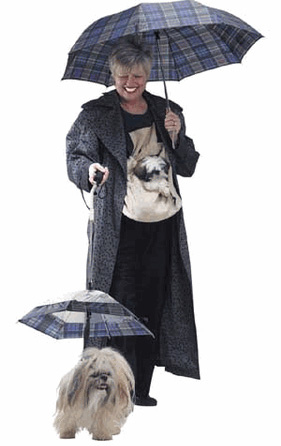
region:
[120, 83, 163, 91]
wide grin on woman's face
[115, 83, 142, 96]
lipstick on woman's face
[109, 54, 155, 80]
blond bangs on woman's face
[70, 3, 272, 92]
large gray and blue umbrella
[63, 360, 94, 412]
shaggy hair on dog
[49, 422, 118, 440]
dog's foot on the ground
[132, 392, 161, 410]
woman wearing black shoe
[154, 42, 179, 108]
tall handle of umbrella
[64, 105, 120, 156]
blue coat with black spots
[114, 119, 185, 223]
black shirt with dog picture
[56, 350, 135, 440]
this is a dog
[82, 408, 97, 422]
the dog is white in color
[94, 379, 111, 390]
this is the dog's mouth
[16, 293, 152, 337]
this is an umbrella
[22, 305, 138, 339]
the umbrella is open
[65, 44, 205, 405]
this is a woman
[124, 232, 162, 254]
the trouser is black in color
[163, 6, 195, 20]
the umbrella is blue in color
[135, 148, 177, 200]
a drawing on the sweater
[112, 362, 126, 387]
the hair is long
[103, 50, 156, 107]
lady smiling and looking at dog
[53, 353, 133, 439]
brown and white dog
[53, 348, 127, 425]
long hair of dog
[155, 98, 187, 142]
hand of the woman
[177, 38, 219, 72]
pattern on the umbrella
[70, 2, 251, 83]
umbrella over lady's head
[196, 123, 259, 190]
white background of photo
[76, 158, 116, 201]
lady holding a leash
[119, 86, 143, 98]
white teeth of lady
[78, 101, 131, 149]
jacket of lady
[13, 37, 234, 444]
a woman and her dog with matching plaid umbrellas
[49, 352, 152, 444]
a small dog with extremely long white hair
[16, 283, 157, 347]
a tiny blue plaid umbrella for the dog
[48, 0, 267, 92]
a large blue plaid umbrella the lady is holding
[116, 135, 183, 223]
a picture of an animal on the front of the lady's shirt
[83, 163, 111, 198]
the lady's hand holding the handle of the dog leash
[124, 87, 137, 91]
the extremely white teeth of the lady's smile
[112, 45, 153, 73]
the lady's short blonde hair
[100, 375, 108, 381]
the small black nose of the dog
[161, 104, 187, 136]
the lady's hand clutching the umbrella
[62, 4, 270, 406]
lady and dog with umbrellas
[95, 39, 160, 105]
lady with big smile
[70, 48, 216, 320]
lady wearing gray and black coat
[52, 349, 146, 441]
white dog with fluffy hair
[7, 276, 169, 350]
purple and gray trimmed umbrella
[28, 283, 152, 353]
clear plastic top on umbrella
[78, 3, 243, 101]
gray and purple plaid umbrella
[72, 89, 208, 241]
shirt with dog picture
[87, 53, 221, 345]
lady wearing black pants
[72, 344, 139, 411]
dog has black nose